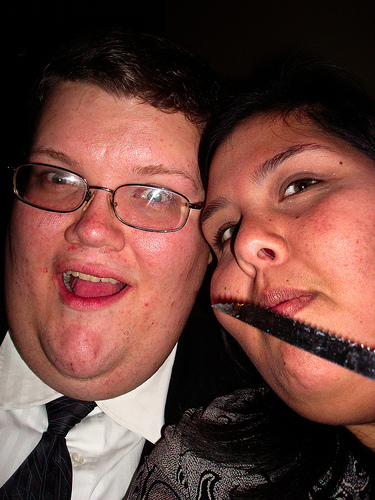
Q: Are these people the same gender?
A: No, they are both male and female.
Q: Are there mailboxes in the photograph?
A: No, there are no mailboxes.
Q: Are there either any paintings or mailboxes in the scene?
A: No, there are no mailboxes or paintings.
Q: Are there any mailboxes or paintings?
A: No, there are no mailboxes or paintings.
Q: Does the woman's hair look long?
A: Yes, the hair is long.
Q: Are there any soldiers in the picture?
A: No, there are no soldiers.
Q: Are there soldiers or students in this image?
A: No, there are no soldiers or students.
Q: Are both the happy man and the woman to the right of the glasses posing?
A: Yes, both the man and the woman are posing.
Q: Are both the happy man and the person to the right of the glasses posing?
A: Yes, both the man and the woman are posing.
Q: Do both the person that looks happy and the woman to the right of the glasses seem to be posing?
A: Yes, both the man and the woman are posing.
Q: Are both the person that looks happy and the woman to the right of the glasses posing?
A: Yes, both the man and the woman are posing.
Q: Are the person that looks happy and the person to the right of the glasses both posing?
A: Yes, both the man and the woman are posing.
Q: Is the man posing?
A: Yes, the man is posing.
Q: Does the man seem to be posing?
A: Yes, the man is posing.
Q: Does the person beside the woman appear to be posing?
A: Yes, the man is posing.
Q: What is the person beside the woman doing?
A: The man is posing.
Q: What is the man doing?
A: The man is posing.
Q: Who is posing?
A: The man is posing.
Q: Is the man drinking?
A: No, the man is posing.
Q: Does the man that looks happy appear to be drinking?
A: No, the man is posing.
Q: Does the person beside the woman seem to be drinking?
A: No, the man is posing.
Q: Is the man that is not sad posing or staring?
A: The man is posing.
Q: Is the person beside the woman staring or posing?
A: The man is posing.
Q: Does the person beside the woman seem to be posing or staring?
A: The man is posing.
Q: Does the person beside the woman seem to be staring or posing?
A: The man is posing.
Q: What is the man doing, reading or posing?
A: The man is posing.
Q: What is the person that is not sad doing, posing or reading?
A: The man is posing.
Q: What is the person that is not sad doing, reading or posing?
A: The man is posing.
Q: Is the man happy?
A: Yes, the man is happy.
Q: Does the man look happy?
A: Yes, the man is happy.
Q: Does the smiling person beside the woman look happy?
A: Yes, the man is happy.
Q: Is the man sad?
A: No, the man is happy.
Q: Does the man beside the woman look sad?
A: No, the man is happy.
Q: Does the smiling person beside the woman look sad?
A: No, the man is happy.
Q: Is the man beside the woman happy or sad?
A: The man is happy.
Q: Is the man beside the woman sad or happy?
A: The man is happy.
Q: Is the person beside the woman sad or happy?
A: The man is happy.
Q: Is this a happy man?
A: Yes, this is a happy man.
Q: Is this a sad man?
A: No, this is a happy man.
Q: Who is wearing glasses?
A: The man is wearing glasses.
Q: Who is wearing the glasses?
A: The man is wearing glasses.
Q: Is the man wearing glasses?
A: Yes, the man is wearing glasses.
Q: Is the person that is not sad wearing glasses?
A: Yes, the man is wearing glasses.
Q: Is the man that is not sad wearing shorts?
A: No, the man is wearing glasses.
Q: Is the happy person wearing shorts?
A: No, the man is wearing glasses.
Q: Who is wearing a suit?
A: The man is wearing a suit.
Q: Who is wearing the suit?
A: The man is wearing a suit.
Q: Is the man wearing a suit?
A: Yes, the man is wearing a suit.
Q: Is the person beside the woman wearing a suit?
A: Yes, the man is wearing a suit.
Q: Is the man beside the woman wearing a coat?
A: No, the man is wearing a suit.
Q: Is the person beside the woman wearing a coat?
A: No, the man is wearing a suit.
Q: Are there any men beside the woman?
A: Yes, there is a man beside the woman.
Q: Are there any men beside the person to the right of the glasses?
A: Yes, there is a man beside the woman.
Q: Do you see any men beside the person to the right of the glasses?
A: Yes, there is a man beside the woman.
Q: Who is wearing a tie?
A: The man is wearing a tie.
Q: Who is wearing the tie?
A: The man is wearing a tie.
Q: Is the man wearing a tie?
A: Yes, the man is wearing a tie.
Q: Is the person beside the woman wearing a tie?
A: Yes, the man is wearing a tie.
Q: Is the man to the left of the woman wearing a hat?
A: No, the man is wearing a tie.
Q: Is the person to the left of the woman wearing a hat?
A: No, the man is wearing a tie.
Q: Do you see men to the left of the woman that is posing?
A: Yes, there is a man to the left of the woman.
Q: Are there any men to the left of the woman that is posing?
A: Yes, there is a man to the left of the woman.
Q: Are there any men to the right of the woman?
A: No, the man is to the left of the woman.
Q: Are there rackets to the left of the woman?
A: No, there is a man to the left of the woman.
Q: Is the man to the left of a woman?
A: Yes, the man is to the left of a woman.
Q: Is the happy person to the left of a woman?
A: Yes, the man is to the left of a woman.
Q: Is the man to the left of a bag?
A: No, the man is to the left of a woman.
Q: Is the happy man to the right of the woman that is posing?
A: No, the man is to the left of the woman.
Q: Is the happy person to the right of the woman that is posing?
A: No, the man is to the left of the woman.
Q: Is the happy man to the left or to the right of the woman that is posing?
A: The man is to the left of the woman.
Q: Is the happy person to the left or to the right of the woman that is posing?
A: The man is to the left of the woman.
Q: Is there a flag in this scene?
A: No, there are no flags.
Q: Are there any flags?
A: No, there are no flags.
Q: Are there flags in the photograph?
A: No, there are no flags.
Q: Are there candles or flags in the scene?
A: No, there are no flags or candles.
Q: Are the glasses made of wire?
A: Yes, the glasses are made of wire.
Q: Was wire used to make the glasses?
A: Yes, the glasses are made of wire.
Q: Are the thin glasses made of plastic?
A: No, the glasses are made of wire.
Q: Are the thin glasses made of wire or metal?
A: The glasses are made of wire.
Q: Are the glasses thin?
A: Yes, the glasses are thin.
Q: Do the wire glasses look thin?
A: Yes, the glasses are thin.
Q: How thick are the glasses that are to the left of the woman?
A: The glasses are thin.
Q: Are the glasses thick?
A: No, the glasses are thin.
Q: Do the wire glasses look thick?
A: No, the glasses are thin.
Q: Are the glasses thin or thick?
A: The glasses are thin.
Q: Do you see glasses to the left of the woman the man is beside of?
A: Yes, there are glasses to the left of the woman.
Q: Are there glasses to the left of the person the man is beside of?
A: Yes, there are glasses to the left of the woman.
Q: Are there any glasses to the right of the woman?
A: No, the glasses are to the left of the woman.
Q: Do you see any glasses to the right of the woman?
A: No, the glasses are to the left of the woman.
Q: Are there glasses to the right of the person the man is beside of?
A: No, the glasses are to the left of the woman.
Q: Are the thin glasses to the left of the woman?
A: Yes, the glasses are to the left of the woman.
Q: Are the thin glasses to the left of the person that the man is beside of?
A: Yes, the glasses are to the left of the woman.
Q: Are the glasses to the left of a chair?
A: No, the glasses are to the left of the woman.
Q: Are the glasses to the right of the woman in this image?
A: No, the glasses are to the left of the woman.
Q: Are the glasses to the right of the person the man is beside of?
A: No, the glasses are to the left of the woman.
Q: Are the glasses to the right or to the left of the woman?
A: The glasses are to the left of the woman.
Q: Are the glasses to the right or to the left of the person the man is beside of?
A: The glasses are to the left of the woman.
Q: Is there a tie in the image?
A: Yes, there is a tie.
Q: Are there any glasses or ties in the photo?
A: Yes, there is a tie.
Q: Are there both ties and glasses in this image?
A: Yes, there are both a tie and glasses.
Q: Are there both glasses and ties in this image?
A: Yes, there are both a tie and glasses.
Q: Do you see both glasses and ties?
A: Yes, there are both a tie and glasses.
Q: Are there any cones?
A: No, there are no cones.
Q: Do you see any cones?
A: No, there are no cones.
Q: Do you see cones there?
A: No, there are no cones.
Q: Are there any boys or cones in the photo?
A: No, there are no cones or boys.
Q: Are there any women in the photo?
A: Yes, there is a woman.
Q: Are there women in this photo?
A: Yes, there is a woman.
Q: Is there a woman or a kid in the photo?
A: Yes, there is a woman.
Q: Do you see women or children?
A: Yes, there is a woman.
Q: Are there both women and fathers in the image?
A: No, there is a woman but no fathers.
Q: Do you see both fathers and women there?
A: No, there is a woman but no fathers.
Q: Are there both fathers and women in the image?
A: No, there is a woman but no fathers.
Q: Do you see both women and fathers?
A: No, there is a woman but no fathers.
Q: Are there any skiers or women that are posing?
A: Yes, the woman is posing.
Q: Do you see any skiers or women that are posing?
A: Yes, the woman is posing.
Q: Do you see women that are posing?
A: Yes, there is a woman that is posing.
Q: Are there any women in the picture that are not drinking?
A: Yes, there is a woman that is posing.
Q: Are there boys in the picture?
A: No, there are no boys.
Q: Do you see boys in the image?
A: No, there are no boys.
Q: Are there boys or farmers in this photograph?
A: No, there are no boys or farmers.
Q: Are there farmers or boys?
A: No, there are no boys or farmers.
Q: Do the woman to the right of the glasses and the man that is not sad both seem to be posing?
A: Yes, both the woman and the man are posing.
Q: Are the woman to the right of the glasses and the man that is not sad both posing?
A: Yes, both the woman and the man are posing.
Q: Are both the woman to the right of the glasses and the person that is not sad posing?
A: Yes, both the woman and the man are posing.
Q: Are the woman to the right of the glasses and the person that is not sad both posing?
A: Yes, both the woman and the man are posing.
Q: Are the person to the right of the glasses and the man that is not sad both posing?
A: Yes, both the woman and the man are posing.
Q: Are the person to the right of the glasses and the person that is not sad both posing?
A: Yes, both the woman and the man are posing.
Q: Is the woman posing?
A: Yes, the woman is posing.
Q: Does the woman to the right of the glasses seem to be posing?
A: Yes, the woman is posing.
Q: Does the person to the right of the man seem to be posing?
A: Yes, the woman is posing.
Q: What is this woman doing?
A: The woman is posing.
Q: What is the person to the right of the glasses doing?
A: The woman is posing.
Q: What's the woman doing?
A: The woman is posing.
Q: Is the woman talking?
A: No, the woman is posing.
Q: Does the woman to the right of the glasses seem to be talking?
A: No, the woman is posing.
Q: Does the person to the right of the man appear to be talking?
A: No, the woman is posing.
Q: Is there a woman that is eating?
A: No, there is a woman but she is posing.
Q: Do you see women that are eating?
A: No, there is a woman but she is posing.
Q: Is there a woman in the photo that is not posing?
A: No, there is a woman but she is posing.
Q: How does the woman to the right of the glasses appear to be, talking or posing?
A: The woman is posing.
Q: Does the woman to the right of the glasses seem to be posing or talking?
A: The woman is posing.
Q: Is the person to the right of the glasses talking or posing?
A: The woman is posing.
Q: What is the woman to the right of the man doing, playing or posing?
A: The woman is posing.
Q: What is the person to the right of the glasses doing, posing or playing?
A: The woman is posing.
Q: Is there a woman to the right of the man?
A: Yes, there is a woman to the right of the man.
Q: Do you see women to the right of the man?
A: Yes, there is a woman to the right of the man.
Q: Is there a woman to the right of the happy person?
A: Yes, there is a woman to the right of the man.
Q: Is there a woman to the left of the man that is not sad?
A: No, the woman is to the right of the man.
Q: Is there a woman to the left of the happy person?
A: No, the woman is to the right of the man.